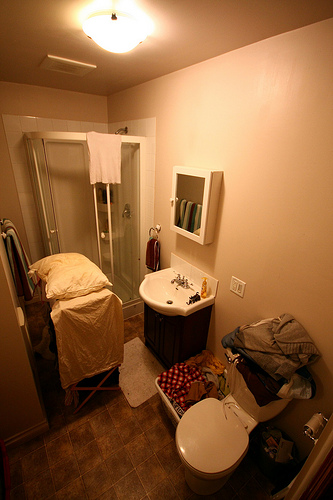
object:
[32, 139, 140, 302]
door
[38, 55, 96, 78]
ventilation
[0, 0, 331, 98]
ceiling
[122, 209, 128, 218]
water handle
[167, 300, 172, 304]
drain hole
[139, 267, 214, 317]
basin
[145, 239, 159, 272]
hand towel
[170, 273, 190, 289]
taps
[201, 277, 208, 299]
soap bottle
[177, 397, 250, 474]
toilet cover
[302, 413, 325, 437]
toilet roll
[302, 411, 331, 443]
mounting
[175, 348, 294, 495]
toilet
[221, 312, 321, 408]
pile of clothes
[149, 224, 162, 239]
towel holder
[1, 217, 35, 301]
towel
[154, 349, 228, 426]
laundry basket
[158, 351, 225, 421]
clothes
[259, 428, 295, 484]
trash can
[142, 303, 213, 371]
cabinet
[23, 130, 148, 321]
shower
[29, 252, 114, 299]
pillow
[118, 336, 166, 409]
rug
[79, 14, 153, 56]
light fixture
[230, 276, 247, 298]
light switch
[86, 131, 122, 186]
towel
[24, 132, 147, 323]
bath tile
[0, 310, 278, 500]
floor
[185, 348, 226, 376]
garment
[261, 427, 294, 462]
trash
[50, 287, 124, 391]
sheet